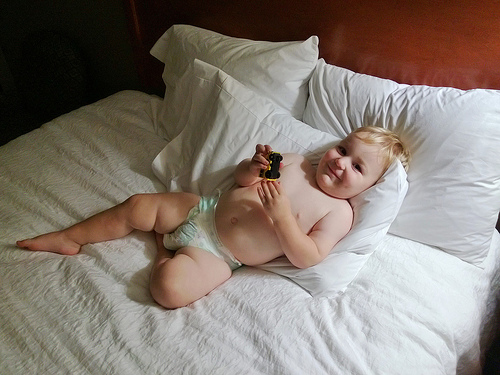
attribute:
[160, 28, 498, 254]
pillow — white, large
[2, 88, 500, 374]
bed — white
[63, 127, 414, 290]
baby — blonde, large, chubby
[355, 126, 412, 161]
hair — blonde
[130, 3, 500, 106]
headboard — brown